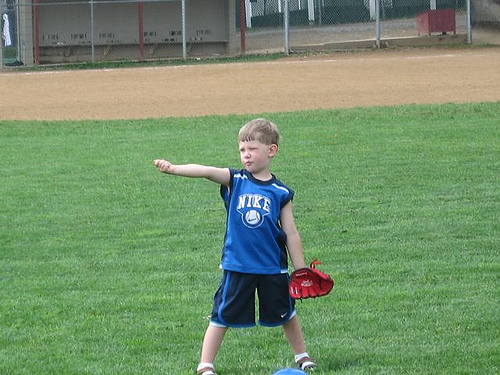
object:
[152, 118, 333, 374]
boy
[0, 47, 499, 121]
dirt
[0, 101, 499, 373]
infield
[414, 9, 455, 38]
bin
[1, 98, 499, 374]
grass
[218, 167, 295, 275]
jersey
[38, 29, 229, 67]
bench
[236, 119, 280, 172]
head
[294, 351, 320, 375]
sandal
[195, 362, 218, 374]
sandal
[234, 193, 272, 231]
logo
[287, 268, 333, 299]
hand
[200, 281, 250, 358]
legs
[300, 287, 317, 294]
red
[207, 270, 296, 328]
shorts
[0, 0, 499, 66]
fence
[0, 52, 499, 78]
line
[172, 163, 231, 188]
arm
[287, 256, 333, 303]
mitt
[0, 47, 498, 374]
baseball field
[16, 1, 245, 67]
dugout